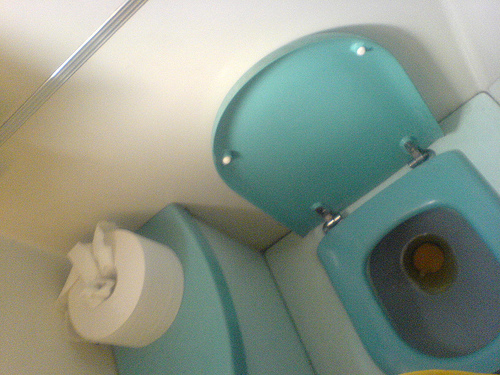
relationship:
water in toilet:
[404, 235, 458, 296] [210, 33, 497, 358]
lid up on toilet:
[210, 28, 445, 240] [210, 33, 497, 358]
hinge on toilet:
[403, 135, 433, 170] [210, 33, 497, 358]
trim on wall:
[1, 1, 141, 146] [5, 3, 498, 243]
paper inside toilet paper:
[61, 212, 117, 304] [61, 224, 181, 348]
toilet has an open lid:
[210, 33, 497, 358] [210, 28, 445, 240]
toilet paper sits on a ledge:
[61, 224, 181, 348] [112, 201, 234, 373]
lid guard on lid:
[357, 44, 369, 61] [210, 28, 445, 240]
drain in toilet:
[414, 242, 444, 281] [210, 33, 497, 358]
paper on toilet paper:
[61, 212, 117, 304] [61, 224, 181, 348]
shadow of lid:
[360, 16, 469, 132] [210, 28, 445, 240]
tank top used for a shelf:
[105, 201, 248, 374] [112, 201, 234, 373]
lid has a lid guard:
[210, 28, 445, 240] [221, 153, 235, 167]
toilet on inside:
[210, 33, 497, 358] [366, 202, 499, 360]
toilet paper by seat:
[61, 224, 181, 348] [315, 148, 500, 374]